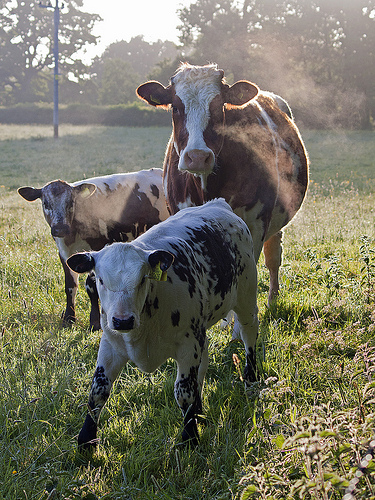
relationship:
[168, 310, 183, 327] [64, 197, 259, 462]
blackspot on cow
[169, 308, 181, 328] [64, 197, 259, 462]
spot on cow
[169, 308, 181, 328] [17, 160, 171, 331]
spot on cow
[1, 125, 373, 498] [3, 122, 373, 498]
field of grass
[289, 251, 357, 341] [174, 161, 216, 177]
grass in cow's mouth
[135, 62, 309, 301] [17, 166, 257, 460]
cow with calves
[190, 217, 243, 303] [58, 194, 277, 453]
spot on side of cow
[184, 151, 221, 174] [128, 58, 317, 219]
nose of cow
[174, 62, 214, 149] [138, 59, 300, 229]
white marking on cow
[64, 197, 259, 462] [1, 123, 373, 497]
cow in grassy field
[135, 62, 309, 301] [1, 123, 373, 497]
cow in grassy field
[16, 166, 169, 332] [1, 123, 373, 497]
cow in grassy field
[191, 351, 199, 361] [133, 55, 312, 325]
spot on a cows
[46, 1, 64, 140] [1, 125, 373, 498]
pole in middle of field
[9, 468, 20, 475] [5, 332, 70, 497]
flower in grass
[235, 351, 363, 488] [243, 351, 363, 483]
flowers on weeds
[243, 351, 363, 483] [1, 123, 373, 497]
weeds in grassy field